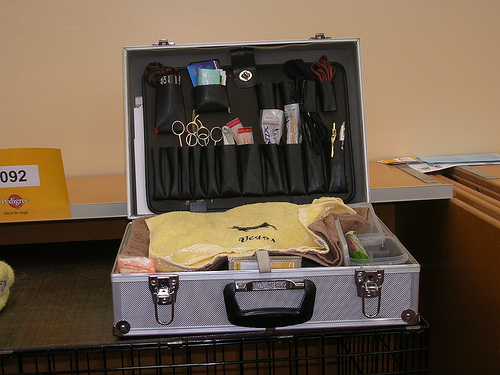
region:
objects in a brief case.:
[103, 31, 426, 342]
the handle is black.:
[213, 274, 318, 334]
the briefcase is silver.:
[100, 35, 426, 342]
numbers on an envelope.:
[1, 142, 66, 219]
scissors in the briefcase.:
[170, 112, 218, 149]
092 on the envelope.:
[0, 164, 43, 189]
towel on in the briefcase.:
[148, 190, 357, 270]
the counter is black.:
[1, 232, 286, 352]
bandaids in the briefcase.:
[225, 114, 255, 151]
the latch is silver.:
[351, 264, 386, 319]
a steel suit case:
[97, 31, 433, 350]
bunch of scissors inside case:
[168, 119, 230, 196]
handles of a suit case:
[219, 277, 321, 330]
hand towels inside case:
[137, 193, 348, 273]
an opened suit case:
[83, 33, 430, 336]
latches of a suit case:
[342, 258, 397, 316]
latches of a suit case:
[145, 268, 190, 330]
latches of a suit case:
[153, 36, 178, 48]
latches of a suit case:
[303, 26, 337, 44]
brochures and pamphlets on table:
[375, 126, 497, 174]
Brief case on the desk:
[110, 32, 425, 335]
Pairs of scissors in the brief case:
[170, 120, 221, 150]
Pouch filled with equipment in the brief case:
[140, 60, 355, 213]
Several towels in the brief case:
[117, 195, 367, 270]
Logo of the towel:
[226, 220, 281, 243]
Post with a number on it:
[0, 148, 75, 222]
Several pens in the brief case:
[326, 118, 346, 155]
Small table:
[1, 243, 429, 372]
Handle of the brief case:
[218, 280, 318, 327]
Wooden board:
[0, 158, 458, 220]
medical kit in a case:
[117, 43, 432, 354]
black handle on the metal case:
[219, 276, 321, 322]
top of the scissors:
[176, 113, 222, 148]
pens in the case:
[326, 116, 348, 162]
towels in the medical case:
[133, 199, 339, 277]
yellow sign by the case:
[5, 140, 80, 227]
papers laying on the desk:
[399, 155, 487, 183]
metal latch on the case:
[350, 270, 390, 322]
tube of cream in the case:
[263, 110, 285, 152]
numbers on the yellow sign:
[1, 170, 29, 182]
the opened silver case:
[109, 37, 419, 336]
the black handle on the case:
[222, 279, 316, 326]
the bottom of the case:
[109, 206, 421, 338]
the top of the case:
[122, 37, 370, 219]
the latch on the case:
[147, 275, 179, 325]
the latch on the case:
[355, 269, 385, 319]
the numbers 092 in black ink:
[0, 168, 26, 183]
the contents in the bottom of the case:
[116, 194, 406, 271]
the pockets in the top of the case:
[141, 60, 355, 213]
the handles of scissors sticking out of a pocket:
[170, 114, 222, 146]